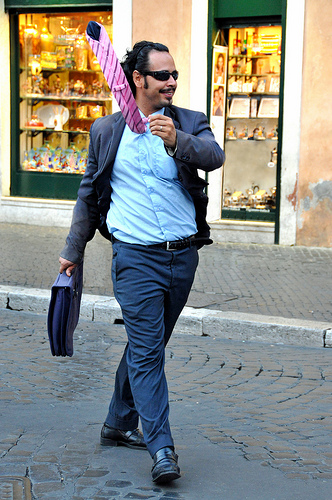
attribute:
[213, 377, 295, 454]
pavement — wet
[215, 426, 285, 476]
pavement — wet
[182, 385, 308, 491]
pavement — wet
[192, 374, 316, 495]
pavement — wet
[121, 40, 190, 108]
person face — smiling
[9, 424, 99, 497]
ground — clean , neat  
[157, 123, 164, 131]
silver ring — silver 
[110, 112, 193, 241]
shirt — button-down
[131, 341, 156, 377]
pants — blue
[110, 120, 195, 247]
shirt — light blue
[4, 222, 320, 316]
sidewalk — BRICK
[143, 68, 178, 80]
sunglasses — BLACK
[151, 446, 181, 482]
shoe — BLACK, LEATHER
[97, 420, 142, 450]
shoe — LEATHER, BLACK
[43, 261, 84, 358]
briefcase — BLUE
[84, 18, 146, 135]
tie — PURPLE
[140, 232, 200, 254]
belt — BLACK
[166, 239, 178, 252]
buckle — SILVER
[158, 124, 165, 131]
ring — SILVER